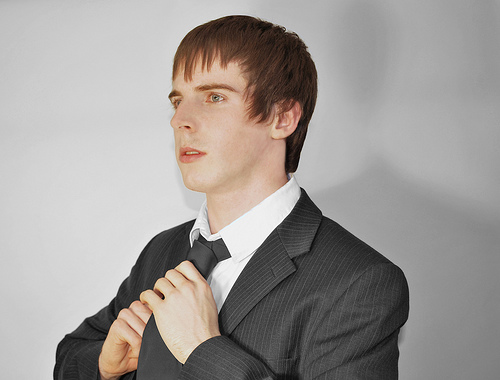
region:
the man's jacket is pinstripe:
[43, 180, 430, 379]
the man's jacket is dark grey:
[32, 180, 432, 378]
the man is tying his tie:
[131, 232, 245, 378]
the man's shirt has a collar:
[177, 171, 326, 268]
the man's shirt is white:
[167, 165, 305, 340]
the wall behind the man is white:
[0, 0, 498, 378]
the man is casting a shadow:
[278, 3, 498, 378]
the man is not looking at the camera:
[22, 6, 423, 378]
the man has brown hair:
[166, 7, 318, 194]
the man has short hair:
[171, 5, 318, 212]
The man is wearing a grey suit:
[26, 18, 414, 362]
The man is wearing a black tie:
[138, 217, 250, 362]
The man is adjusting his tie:
[56, 33, 420, 375]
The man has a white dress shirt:
[63, 40, 412, 360]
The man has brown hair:
[141, 31, 336, 218]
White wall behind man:
[33, 30, 439, 325]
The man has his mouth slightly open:
[47, 31, 437, 357]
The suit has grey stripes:
[53, 197, 408, 372]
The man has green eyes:
[157, 67, 243, 142]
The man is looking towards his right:
[50, 37, 418, 365]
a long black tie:
[118, 220, 239, 367]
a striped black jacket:
[51, 195, 411, 379]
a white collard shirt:
[144, 184, 327, 343]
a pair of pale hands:
[70, 265, 237, 362]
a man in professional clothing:
[31, 17, 441, 368]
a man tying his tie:
[18, 18, 428, 375]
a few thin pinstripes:
[275, 232, 382, 342]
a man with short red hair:
[148, 20, 342, 202]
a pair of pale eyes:
[167, 77, 242, 111]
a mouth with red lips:
[168, 140, 218, 170]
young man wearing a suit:
[39, 8, 426, 377]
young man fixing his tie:
[59, 13, 434, 379]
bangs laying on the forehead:
[166, 31, 239, 84]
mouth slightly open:
[172, 146, 205, 168]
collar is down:
[240, 210, 357, 297]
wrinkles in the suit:
[310, 308, 398, 368]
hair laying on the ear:
[270, 91, 306, 141]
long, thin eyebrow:
[198, 81, 245, 96]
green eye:
[202, 85, 230, 108]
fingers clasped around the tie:
[130, 263, 220, 333]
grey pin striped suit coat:
[212, 181, 445, 373]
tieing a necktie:
[138, 212, 229, 379]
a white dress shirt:
[169, 168, 304, 288]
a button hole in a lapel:
[262, 254, 286, 289]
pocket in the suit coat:
[242, 335, 302, 379]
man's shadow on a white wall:
[282, 0, 477, 257]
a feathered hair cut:
[168, 5, 318, 180]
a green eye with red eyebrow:
[194, 74, 242, 118]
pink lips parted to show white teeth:
[169, 140, 214, 166]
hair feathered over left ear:
[270, 77, 305, 149]